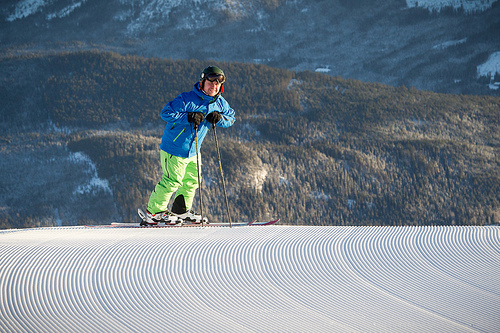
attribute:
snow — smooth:
[131, 233, 479, 304]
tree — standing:
[262, 89, 445, 156]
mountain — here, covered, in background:
[26, 35, 498, 253]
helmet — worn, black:
[189, 60, 249, 92]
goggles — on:
[204, 68, 228, 84]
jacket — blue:
[141, 85, 258, 162]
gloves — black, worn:
[181, 106, 206, 124]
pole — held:
[191, 119, 219, 237]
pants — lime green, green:
[126, 140, 214, 226]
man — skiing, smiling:
[127, 39, 244, 225]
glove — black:
[197, 106, 239, 131]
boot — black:
[136, 191, 200, 228]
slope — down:
[211, 205, 498, 238]